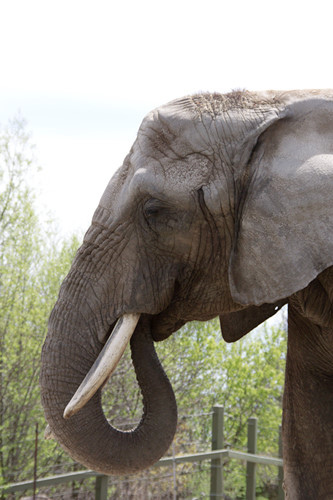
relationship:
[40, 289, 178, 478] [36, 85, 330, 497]
trunk of elephant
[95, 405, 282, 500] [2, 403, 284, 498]
post of gate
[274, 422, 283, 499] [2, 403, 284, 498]
post of gate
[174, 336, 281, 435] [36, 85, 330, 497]
trees behind elephant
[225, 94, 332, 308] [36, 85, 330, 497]
ear of elephant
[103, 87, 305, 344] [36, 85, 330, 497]
elephant head od elephant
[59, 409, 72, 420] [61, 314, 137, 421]
tip of tusk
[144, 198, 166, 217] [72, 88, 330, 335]
eye on side of head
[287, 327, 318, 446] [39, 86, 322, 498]
part body of body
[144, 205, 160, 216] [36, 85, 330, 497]
eye of elephant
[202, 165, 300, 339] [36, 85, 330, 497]
ear of elephant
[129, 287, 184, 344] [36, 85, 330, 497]
mouth of elephant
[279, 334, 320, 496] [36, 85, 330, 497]
leg of elephant